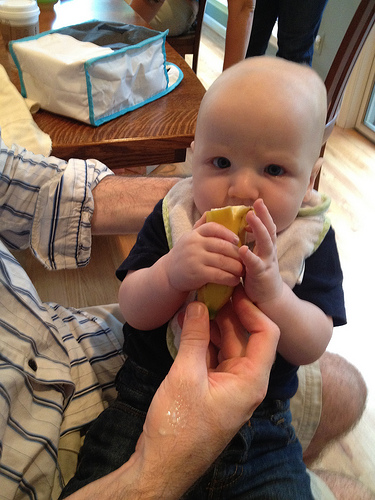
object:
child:
[60, 57, 350, 500]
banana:
[190, 201, 254, 314]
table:
[0, 1, 210, 177]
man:
[0, 132, 375, 500]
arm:
[0, 142, 194, 240]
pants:
[247, 1, 331, 70]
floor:
[0, 38, 375, 499]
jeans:
[59, 365, 313, 499]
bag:
[11, 16, 185, 124]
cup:
[2, 3, 41, 53]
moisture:
[156, 400, 187, 440]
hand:
[132, 305, 282, 486]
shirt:
[2, 132, 134, 490]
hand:
[166, 219, 240, 292]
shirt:
[111, 196, 346, 395]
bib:
[158, 171, 330, 364]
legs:
[286, 353, 369, 469]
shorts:
[288, 351, 330, 499]